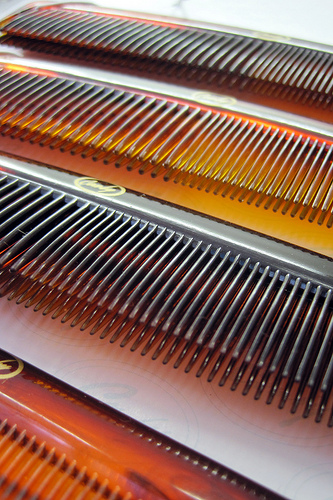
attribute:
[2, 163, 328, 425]
comb — brown, fine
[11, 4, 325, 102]
comb — dark brown